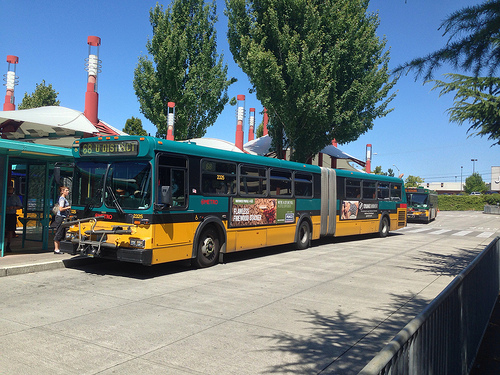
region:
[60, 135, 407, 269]
Large two car mass transit bus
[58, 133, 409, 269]
Peacock green and yellow bus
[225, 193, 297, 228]
Advertisement banner on a bus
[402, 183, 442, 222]
Green and yellow bus behind another bus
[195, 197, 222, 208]
Red lettering on the side of a bus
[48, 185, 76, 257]
Woman getting ready to board a bus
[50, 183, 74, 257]
Woman in a blue shirt and gray bottoms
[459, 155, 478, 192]
Two tall parking lot lamps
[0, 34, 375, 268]
Large bus station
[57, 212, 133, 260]
Bicycle rack on the front of a bus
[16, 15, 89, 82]
the sky is clear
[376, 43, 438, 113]
the sky is clear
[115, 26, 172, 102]
the sky is clear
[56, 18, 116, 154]
the pole is red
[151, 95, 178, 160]
the pole is red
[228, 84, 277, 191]
the pole is red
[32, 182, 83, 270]
a woman at the bus station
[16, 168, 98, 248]
a woman at the bus station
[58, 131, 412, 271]
A long blue and yellow bus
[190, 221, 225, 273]
A black and round tire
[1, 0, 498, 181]
A clear and blue sky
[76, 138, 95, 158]
Number 68 on the bus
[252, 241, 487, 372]
Tree shadows on the pavement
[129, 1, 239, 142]
A tall green tree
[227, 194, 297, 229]
Sign on side of a bus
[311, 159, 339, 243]
A gray connector binding the bus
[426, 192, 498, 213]
A row of green bushes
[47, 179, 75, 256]
Woman waiting for the bus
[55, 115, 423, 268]
A very long bus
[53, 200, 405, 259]
Bus with a yellow bottom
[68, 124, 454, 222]
A bus with a blue top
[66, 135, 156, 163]
Lighted sign over windshield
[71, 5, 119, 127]
Red poles sticking out of roof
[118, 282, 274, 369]
Large white tile driveway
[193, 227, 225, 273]
Black tire on bus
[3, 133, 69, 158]
Light blue trim on building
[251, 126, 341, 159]
A blue roof on building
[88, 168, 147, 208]
Black windshield wipers on bus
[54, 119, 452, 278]
buses are yellow and blueish green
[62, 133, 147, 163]
yellow letters and numbers on bus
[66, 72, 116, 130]
the part is red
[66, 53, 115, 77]
the part is white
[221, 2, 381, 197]
large tree beside bus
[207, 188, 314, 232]
advertisement on side of bus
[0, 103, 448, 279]
buses stopping at bus stop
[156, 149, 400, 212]
bus windows are black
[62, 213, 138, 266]
bike rack on front of bus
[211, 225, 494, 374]
shadow of tree on ground